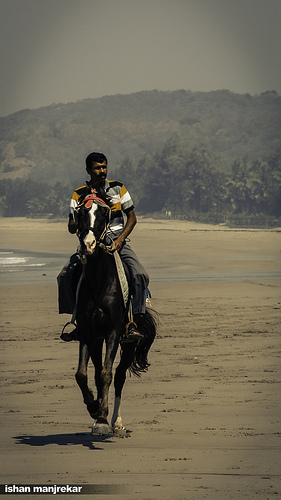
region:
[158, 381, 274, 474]
the dirt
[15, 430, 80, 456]
shadow on the dirt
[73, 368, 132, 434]
the horses leg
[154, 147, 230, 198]
the bush is green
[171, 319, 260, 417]
marks in the sand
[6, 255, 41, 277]
water on the sand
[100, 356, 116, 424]
the horses leg is brown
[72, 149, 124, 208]
a man riding a horse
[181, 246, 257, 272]
the sand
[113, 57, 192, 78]
the sky is grey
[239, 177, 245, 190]
part of a forest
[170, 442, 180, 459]
part of a beach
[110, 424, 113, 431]
part of a hoof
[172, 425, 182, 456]
edge of a beach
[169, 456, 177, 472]
part of a hill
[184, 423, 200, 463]
edge of a hill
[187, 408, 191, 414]
part of the ocean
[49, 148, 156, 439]
man riding on black and white horse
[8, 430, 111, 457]
shadow of horse and man on sand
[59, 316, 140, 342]
stirrups man's feet are in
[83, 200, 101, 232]
white marking on horse's face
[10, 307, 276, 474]
tracks in the sand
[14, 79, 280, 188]
mountain behind the beach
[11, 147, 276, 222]
trees along the sand line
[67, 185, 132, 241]
yellow, black, white, and gray shirt of man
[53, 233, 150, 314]
gray pants of man on horse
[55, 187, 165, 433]
black and white horse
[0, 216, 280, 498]
Sand on the beach.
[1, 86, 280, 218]
Mountains in the background.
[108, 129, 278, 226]
Trees in the background.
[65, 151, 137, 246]
Striped shirt on the man.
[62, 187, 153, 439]
Brown horse on the beach.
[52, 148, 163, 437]
Man riding on horse.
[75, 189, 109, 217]
Red headdress on the horse.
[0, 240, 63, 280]
Water in the sand.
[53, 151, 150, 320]
Gray pants on the man.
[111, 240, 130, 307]
Blanket on the horse.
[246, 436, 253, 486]
part of the sand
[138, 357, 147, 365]
part of a horse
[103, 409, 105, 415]
edge of a leg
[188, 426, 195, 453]
part of the beach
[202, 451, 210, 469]
part of the water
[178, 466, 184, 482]
section of the shore